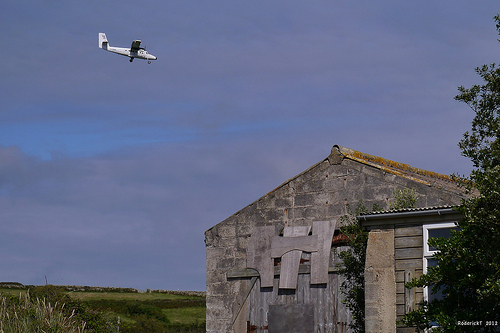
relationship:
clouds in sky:
[4, 7, 498, 288] [7, 0, 494, 290]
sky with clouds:
[7, 0, 494, 290] [4, 7, 498, 288]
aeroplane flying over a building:
[98, 32, 157, 64] [208, 138, 495, 332]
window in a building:
[421, 222, 479, 311] [208, 138, 495, 332]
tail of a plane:
[92, 33, 110, 49] [93, 31, 160, 65]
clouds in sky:
[58, 68, 113, 128] [15, 124, 96, 155]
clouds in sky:
[77, 143, 109, 191] [42, 148, 99, 223]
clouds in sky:
[66, 160, 123, 217] [61, 110, 98, 168]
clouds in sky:
[54, 149, 141, 246] [93, 91, 161, 153]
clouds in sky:
[65, 150, 90, 206] [326, 43, 385, 96]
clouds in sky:
[82, 169, 131, 217] [100, 175, 171, 215]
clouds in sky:
[0, 0, 97, 109] [57, 156, 122, 213]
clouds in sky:
[72, 177, 126, 235] [106, 100, 140, 140]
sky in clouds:
[0, 0, 498, 290] [95, 121, 125, 152]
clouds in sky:
[37, 174, 141, 236] [94, 83, 205, 193]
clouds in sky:
[92, 121, 125, 190] [242, 46, 282, 75]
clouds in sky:
[149, 146, 199, 183] [73, 173, 137, 223]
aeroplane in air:
[98, 32, 157, 64] [127, 160, 217, 195]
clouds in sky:
[0, 0, 97, 109] [66, 111, 114, 162]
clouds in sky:
[185, 120, 220, 155] [86, 156, 119, 199]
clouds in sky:
[96, 193, 133, 230] [85, 136, 100, 170]